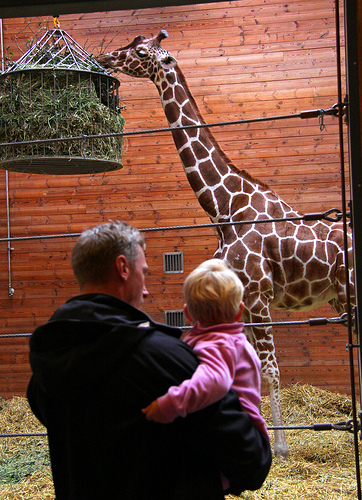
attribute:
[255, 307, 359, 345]
wire — metal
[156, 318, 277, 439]
shirt — pink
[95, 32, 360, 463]
giraffe — eating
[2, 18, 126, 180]
feeder basket — black, metal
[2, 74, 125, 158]
grass — shredded, green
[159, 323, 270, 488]
coat — pink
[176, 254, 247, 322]
hair — blond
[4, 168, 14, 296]
pipe — long, silver, metal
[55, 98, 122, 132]
straw — brown, large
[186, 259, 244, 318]
hair — blond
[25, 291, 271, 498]
jacket — black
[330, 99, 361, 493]
rod — long, metal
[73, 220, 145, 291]
hair — gray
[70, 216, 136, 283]
hair — grey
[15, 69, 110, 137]
grass — green